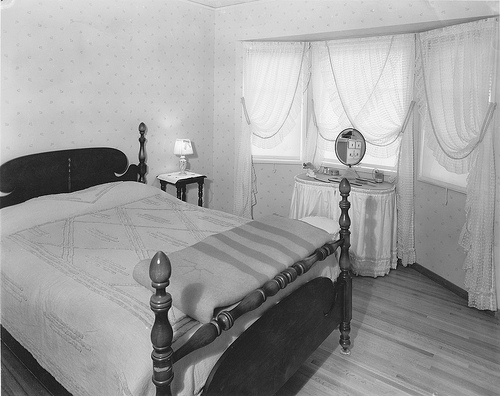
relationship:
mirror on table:
[333, 128, 369, 172] [292, 158, 412, 292]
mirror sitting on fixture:
[329, 128, 371, 170] [340, 166, 363, 182]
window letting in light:
[303, 44, 411, 177] [323, 53, 399, 129]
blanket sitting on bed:
[130, 213, 336, 323] [4, 184, 370, 381]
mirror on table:
[329, 128, 371, 170] [289, 160, 401, 203]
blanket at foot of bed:
[134, 214, 356, 316] [4, 167, 384, 386]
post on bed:
[327, 177, 363, 356] [15, 136, 385, 387]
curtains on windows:
[217, 28, 484, 316] [236, 35, 484, 181]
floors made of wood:
[11, 265, 484, 380] [345, 285, 484, 385]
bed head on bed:
[0, 146, 137, 207] [15, 136, 385, 387]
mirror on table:
[329, 128, 371, 170] [287, 160, 403, 271]